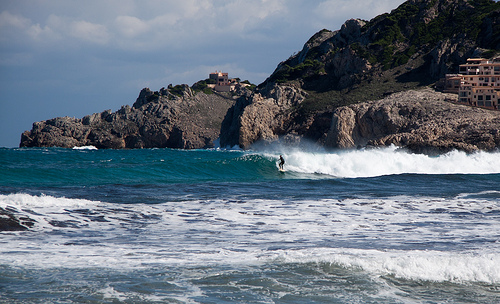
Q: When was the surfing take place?
A: Daytime.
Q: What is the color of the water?
A: Bluegreen.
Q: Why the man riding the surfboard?
A: To surf.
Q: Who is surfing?
A: A man.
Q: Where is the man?
A: On the water.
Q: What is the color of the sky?
A: Blue and white.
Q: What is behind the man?
A: Big rocks.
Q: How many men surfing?
A: One.